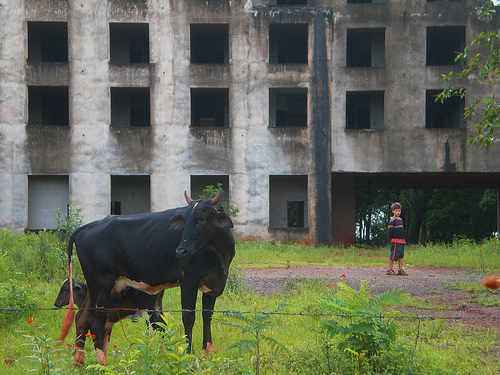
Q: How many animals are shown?
A: Two.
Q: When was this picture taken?
A: In the daytime.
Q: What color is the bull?
A: Black.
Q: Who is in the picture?
A: A young boy.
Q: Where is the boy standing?
A: On a paved area.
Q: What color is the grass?
A: Green.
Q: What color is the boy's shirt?
A: Blue and red.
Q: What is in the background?
A: An old building.